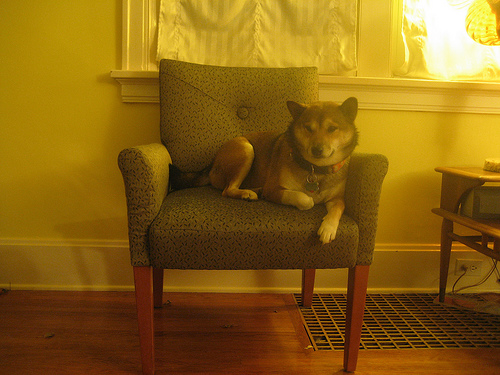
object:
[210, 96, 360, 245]
dog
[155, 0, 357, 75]
window coverings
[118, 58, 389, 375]
chair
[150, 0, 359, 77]
window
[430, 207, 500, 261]
shelf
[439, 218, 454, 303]
leg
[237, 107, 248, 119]
button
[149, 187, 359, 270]
cushions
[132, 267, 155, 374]
legs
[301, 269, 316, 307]
legs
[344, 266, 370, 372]
legs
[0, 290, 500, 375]
floor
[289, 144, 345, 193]
collar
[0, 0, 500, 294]
wall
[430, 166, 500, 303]
end table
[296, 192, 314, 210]
paw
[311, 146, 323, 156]
nose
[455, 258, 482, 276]
cord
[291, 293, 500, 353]
grate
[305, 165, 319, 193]
dog tag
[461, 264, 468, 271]
plug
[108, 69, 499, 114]
window sill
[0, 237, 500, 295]
baseboard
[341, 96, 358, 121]
left ear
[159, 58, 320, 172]
seat cushion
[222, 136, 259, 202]
hind leg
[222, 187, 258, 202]
foot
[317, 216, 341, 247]
front leg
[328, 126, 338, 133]
eye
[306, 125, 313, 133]
eye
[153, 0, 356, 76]
covering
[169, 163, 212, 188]
tail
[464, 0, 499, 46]
lamp shade